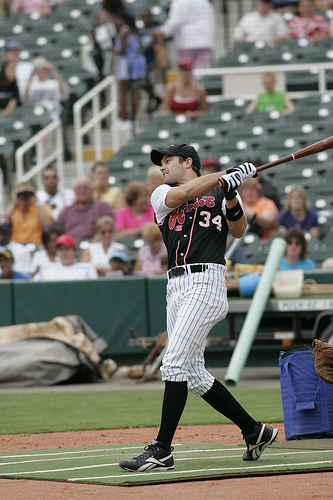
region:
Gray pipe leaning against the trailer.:
[221, 228, 287, 386]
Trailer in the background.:
[117, 275, 327, 356]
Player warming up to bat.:
[112, 134, 327, 488]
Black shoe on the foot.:
[112, 438, 179, 480]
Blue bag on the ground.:
[272, 340, 331, 442]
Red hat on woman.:
[160, 58, 211, 120]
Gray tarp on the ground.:
[0, 312, 120, 384]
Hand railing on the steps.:
[6, 73, 131, 212]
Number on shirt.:
[198, 208, 223, 237]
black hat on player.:
[147, 138, 206, 187]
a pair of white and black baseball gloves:
[222, 162, 257, 190]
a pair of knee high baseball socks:
[153, 379, 255, 442]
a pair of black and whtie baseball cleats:
[120, 424, 276, 472]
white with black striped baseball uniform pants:
[162, 268, 228, 398]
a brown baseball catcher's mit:
[309, 337, 332, 380]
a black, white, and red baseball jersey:
[152, 185, 242, 263]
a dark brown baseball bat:
[219, 132, 331, 182]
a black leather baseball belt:
[166, 267, 205, 274]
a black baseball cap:
[149, 142, 199, 168]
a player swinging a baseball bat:
[118, 137, 332, 470]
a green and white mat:
[7, 438, 328, 486]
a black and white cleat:
[116, 441, 183, 475]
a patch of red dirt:
[10, 415, 325, 498]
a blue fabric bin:
[269, 338, 331, 443]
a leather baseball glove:
[308, 336, 332, 382]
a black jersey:
[147, 178, 247, 267]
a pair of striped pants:
[156, 259, 234, 396]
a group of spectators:
[14, 161, 310, 284]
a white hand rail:
[68, 73, 126, 168]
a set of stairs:
[46, 113, 134, 188]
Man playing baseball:
[113, 120, 325, 480]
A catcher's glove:
[302, 330, 331, 384]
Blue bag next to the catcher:
[278, 341, 332, 433]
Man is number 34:
[199, 209, 227, 239]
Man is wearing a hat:
[147, 134, 207, 169]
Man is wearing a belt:
[161, 266, 228, 283]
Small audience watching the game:
[18, 166, 150, 273]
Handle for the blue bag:
[291, 395, 325, 412]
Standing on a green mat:
[15, 415, 296, 490]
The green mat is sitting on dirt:
[10, 408, 314, 482]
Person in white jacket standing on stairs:
[157, 0, 216, 76]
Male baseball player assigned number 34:
[116, 144, 278, 472]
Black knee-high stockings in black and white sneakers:
[119, 381, 279, 471]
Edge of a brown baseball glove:
[312, 337, 332, 382]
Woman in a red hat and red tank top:
[163, 61, 208, 116]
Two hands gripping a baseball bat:
[216, 135, 332, 192]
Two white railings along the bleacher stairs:
[14, 73, 118, 198]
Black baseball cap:
[149, 143, 202, 168]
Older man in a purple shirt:
[51, 176, 114, 241]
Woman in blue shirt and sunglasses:
[277, 230, 316, 269]